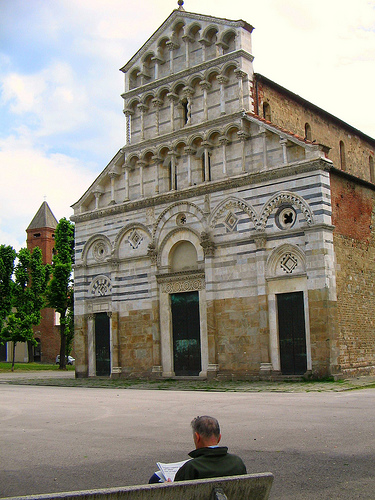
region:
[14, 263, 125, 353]
The leaves are green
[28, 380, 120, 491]
The pavement is gray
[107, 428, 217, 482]
The man is reading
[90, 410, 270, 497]
The man is on a bench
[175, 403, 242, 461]
The man has some gray hair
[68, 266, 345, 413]
The building has 3 doors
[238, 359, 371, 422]
The grass is patchy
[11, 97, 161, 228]
The sky is blue with clouds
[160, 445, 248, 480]
The man has a green jacket on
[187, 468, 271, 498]
The bench is gray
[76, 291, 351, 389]
three sets of double doors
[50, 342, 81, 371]
vehicle behind the tree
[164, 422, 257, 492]
man sitting on a bench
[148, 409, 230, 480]
man is reading the paper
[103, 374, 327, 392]
weeds and moss growing on walkway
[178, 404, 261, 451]
man has grey hair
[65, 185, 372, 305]
stripes on this section of the building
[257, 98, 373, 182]
four windows on side of building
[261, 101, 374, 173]
windows are arched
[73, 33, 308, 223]
small pillars on the building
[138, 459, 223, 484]
MAN READING A NEWSPAPER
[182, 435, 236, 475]
MAN IS WEARING A GREEN JACKET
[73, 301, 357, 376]
THREE DOORS ARE ON FRONT OF BUILDING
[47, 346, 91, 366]
SINGLE CAR TO THE LEFT OF BUILDING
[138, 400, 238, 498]
A MAN SITS ON A BENCH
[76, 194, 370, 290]
MULTIPLE ARCHES ARE ON FRONT OF BUILDING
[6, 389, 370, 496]
ROAD IS OF A GREY COLOR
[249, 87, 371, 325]
SIDE OF BUILDING CONSIST OF BRICK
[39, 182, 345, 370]
BUILDING FRONT IS TAN IN COLOR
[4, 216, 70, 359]
TREES TO LEFT OF BUILDING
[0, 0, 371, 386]
A large old building or church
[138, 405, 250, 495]
A man sitting on a bench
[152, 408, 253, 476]
A man reading a newspaper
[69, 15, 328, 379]
a large old building or church with three doors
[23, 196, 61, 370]
A red brick building on left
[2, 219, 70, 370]
Three green trees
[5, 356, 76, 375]
A green yard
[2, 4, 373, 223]
Blue clouds in the sky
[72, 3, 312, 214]
Design on top of white part of building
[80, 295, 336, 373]
green doors on building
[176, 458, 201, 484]
a man reading paper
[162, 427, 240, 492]
a man reading paper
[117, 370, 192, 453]
a man reading paper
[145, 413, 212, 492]
a man reading paper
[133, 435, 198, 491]
a man reading paper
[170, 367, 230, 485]
a man reading paper